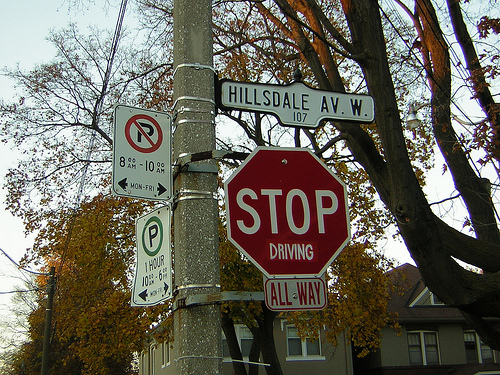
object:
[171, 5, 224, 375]
pole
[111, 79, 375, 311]
signs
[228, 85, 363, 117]
hillsdale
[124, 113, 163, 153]
no-parking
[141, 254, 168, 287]
1-hour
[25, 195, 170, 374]
tree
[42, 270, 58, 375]
pole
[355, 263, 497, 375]
house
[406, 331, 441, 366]
window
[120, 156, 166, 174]
numbers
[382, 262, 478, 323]
roof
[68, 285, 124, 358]
part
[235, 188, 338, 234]
letter